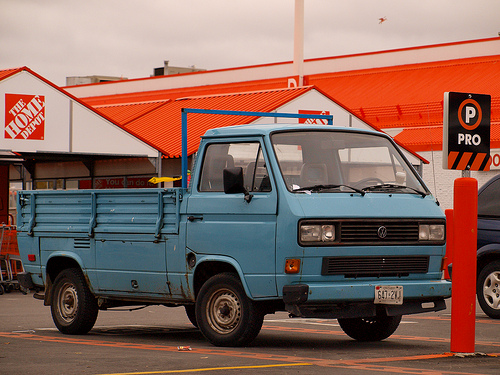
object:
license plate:
[372, 283, 405, 304]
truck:
[14, 106, 453, 346]